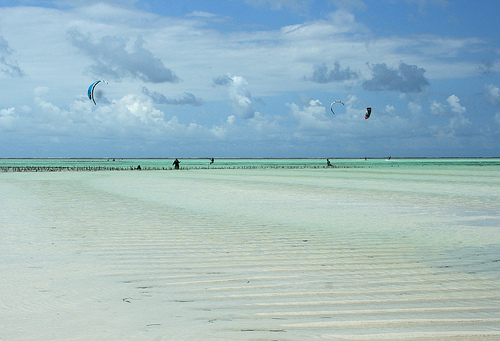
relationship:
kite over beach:
[364, 107, 372, 119] [291, 155, 453, 195]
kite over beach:
[330, 100, 344, 114] [291, 155, 453, 195]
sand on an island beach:
[2, 164, 498, 339] [2, 161, 499, 339]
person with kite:
[206, 151, 217, 166] [87, 79, 103, 105]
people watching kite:
[171, 158, 181, 169] [83, 77, 106, 103]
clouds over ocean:
[0, 9, 499, 157] [0, 156, 497, 339]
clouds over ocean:
[0, 9, 499, 157] [7, 148, 499, 170]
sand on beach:
[2, 164, 498, 339] [2, 161, 499, 339]